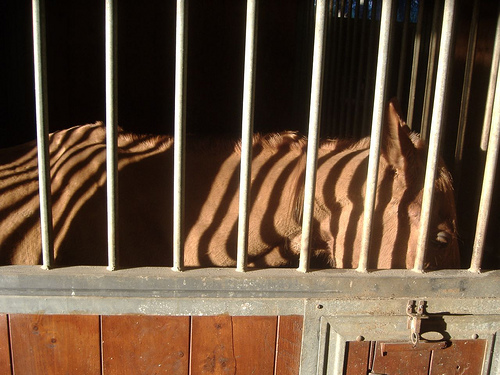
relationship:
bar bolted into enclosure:
[29, 2, 55, 267] [1, 1, 484, 371]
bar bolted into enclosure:
[102, 2, 118, 271] [1, 1, 484, 371]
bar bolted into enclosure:
[169, 2, 185, 270] [1, 1, 484, 371]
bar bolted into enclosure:
[235, 0, 255, 272] [1, 1, 484, 371]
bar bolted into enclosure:
[295, 1, 326, 271] [1, 1, 484, 371]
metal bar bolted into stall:
[296, 0, 327, 273] [0, 0, 497, 375]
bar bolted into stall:
[134, 19, 207, 286] [0, 0, 497, 375]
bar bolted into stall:
[228, 0, 268, 268] [0, 0, 497, 375]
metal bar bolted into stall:
[291, 0, 328, 276] [0, 0, 497, 375]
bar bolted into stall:
[411, 0, 455, 270] [0, 0, 497, 375]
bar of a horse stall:
[411, 0, 455, 270] [0, 1, 497, 268]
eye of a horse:
[433, 228, 455, 244] [4, 69, 465, 278]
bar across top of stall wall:
[235, 0, 255, 272] [159, 276, 396, 360]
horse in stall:
[6, 95, 473, 270] [0, 0, 497, 375]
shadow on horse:
[208, 146, 425, 256] [6, 95, 473, 270]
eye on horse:
[433, 226, 458, 248] [6, 95, 473, 270]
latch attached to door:
[381, 303, 451, 343] [242, 87, 477, 347]